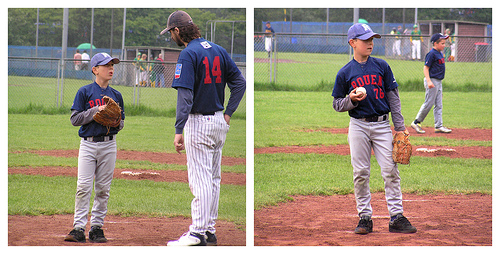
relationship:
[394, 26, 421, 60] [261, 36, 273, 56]
players in pants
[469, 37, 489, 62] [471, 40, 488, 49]
trash can has red lid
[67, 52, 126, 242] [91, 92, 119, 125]
person holding glove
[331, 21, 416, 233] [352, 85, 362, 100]
baseball player holding baseball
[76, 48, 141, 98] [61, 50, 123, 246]
head of person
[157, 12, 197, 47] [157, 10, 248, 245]
head of coach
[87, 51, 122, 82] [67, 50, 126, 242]
head of person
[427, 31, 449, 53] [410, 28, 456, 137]
person's head of person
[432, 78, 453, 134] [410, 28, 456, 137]
leg of person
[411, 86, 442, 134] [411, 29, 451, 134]
leg of person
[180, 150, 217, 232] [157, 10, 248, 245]
leg of coach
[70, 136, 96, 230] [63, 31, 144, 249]
leg of person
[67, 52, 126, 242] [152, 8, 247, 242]
person consults with coach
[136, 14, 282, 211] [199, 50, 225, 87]
coach has number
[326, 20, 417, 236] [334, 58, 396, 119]
pitcher wearing jersey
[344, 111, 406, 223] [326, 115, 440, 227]
pitcher wearing pants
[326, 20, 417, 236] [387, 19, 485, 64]
pitcher warming up in bullpen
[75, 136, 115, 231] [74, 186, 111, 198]
baseball pants with knees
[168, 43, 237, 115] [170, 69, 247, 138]
shirt over shirt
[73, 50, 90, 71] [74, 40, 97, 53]
people walking with umbrella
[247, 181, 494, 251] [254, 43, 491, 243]
sand on ground